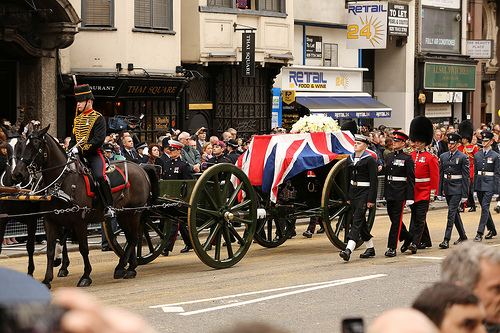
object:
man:
[62, 86, 121, 223]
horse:
[13, 118, 163, 294]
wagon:
[161, 128, 380, 268]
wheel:
[321, 156, 378, 252]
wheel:
[187, 161, 260, 268]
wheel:
[103, 205, 174, 267]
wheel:
[247, 185, 297, 248]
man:
[338, 131, 380, 262]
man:
[381, 128, 416, 257]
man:
[404, 115, 441, 255]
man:
[471, 128, 499, 245]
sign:
[68, 72, 191, 103]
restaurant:
[61, 2, 189, 237]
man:
[156, 138, 196, 258]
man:
[201, 139, 236, 252]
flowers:
[288, 113, 343, 136]